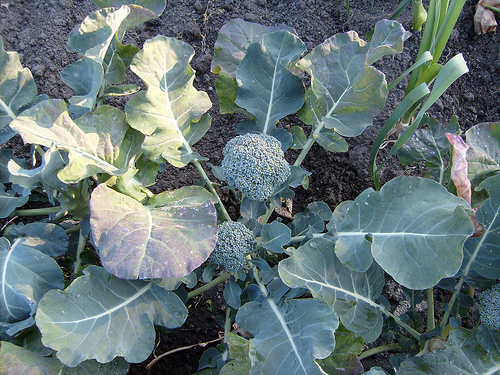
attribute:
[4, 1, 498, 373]
plant — broccoli, growing, green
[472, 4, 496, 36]
leaf — brown, dead, green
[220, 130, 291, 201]
broccoli — growing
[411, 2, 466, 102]
grass — growing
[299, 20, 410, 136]
leaf — green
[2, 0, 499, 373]
dirt — black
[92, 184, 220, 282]
leaf — purple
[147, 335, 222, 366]
twig — dead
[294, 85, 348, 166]
vein — white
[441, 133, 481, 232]
flower — blue, green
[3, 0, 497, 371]
soil — black